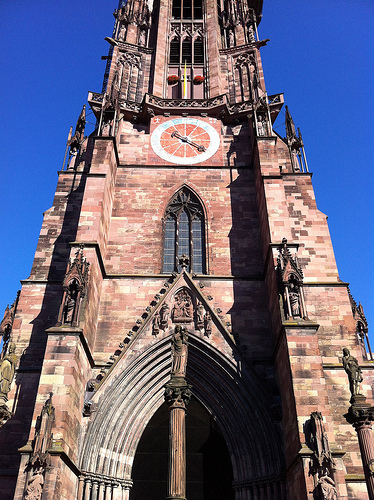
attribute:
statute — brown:
[164, 322, 188, 386]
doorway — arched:
[127, 390, 237, 494]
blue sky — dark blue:
[1, 1, 119, 353]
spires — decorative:
[60, 104, 86, 172]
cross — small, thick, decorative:
[175, 249, 191, 271]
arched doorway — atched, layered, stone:
[123, 386, 241, 495]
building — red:
[291, 331, 347, 418]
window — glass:
[158, 183, 208, 273]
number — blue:
[180, 152, 194, 164]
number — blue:
[171, 117, 182, 124]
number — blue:
[157, 121, 170, 129]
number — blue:
[180, 114, 196, 126]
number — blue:
[202, 125, 208, 130]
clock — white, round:
[139, 106, 230, 169]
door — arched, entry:
[75, 255, 288, 498]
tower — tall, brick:
[0, 5, 373, 489]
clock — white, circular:
[148, 113, 220, 164]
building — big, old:
[23, 6, 361, 497]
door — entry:
[80, 332, 245, 498]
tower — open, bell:
[171, 0, 208, 69]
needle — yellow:
[177, 56, 189, 101]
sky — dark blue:
[253, 0, 373, 352]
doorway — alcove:
[69, 345, 272, 486]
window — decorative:
[147, 171, 222, 278]